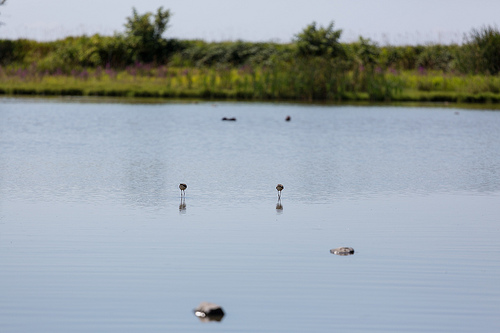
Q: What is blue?
A: Water.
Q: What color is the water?
A: Blue.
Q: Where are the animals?
A: In the lake.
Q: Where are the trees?
A: Background.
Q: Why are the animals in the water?
A: Swimming.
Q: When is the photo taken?
A: Daytime.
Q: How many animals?
A: Six.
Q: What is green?
A: Trees.